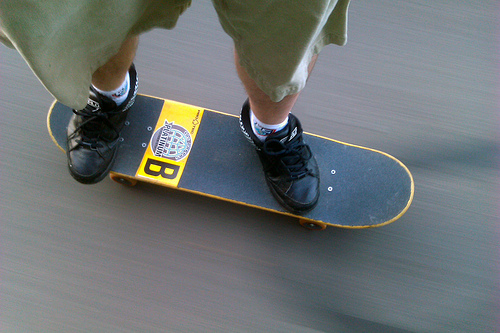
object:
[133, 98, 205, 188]
stripe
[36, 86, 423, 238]
skateboard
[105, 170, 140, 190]
wheel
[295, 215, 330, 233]
wheel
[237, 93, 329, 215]
tennis shoe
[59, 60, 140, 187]
tennis shoe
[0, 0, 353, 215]
man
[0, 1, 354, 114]
shorts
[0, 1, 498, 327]
ground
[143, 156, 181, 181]
letter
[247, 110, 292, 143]
ankle sock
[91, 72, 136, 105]
ankle sock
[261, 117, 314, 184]
shoe lace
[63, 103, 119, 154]
shoe lace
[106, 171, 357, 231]
edge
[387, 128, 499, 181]
shadow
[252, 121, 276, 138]
design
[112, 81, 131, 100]
design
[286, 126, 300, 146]
lettering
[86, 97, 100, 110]
lettering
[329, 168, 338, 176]
grommet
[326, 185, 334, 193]
grommet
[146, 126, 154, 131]
grommet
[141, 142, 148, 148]
grommet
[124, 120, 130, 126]
grommet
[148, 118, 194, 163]
label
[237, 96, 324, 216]
foot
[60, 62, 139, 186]
foot